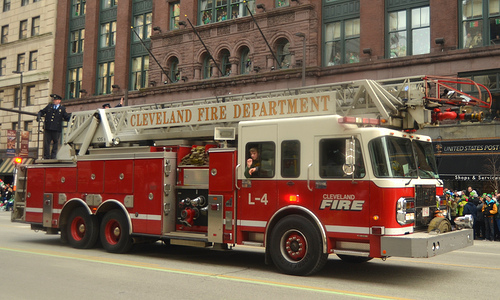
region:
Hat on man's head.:
[48, 84, 81, 133]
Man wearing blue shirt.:
[48, 101, 65, 113]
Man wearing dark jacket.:
[36, 102, 93, 144]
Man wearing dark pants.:
[34, 135, 62, 152]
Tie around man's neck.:
[47, 95, 69, 117]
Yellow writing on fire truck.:
[125, 99, 364, 129]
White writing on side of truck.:
[241, 185, 387, 217]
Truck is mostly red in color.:
[51, 151, 382, 260]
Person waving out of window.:
[228, 137, 265, 174]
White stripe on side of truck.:
[25, 198, 372, 247]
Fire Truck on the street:
[6, 80, 466, 283]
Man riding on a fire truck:
[39, 85, 64, 160]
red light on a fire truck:
[273, 183, 306, 210]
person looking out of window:
[239, 150, 269, 182]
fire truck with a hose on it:
[422, 195, 449, 245]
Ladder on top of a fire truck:
[68, 88, 445, 144]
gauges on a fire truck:
[163, 184, 222, 239]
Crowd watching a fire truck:
[453, 179, 498, 254]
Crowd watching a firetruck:
[433, 155, 490, 239]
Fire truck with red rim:
[272, 215, 334, 277]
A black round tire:
[266, 213, 327, 279]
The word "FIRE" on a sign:
[194, 101, 229, 128]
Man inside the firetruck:
[235, 138, 270, 183]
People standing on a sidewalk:
[448, 183, 498, 243]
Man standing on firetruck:
[33, 88, 74, 163]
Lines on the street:
[1, 239, 410, 298]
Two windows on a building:
[319, 3, 431, 72]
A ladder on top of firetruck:
[58, 75, 407, 146]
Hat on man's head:
[46, 88, 66, 105]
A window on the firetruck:
[277, 135, 305, 182]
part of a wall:
[443, 242, 448, 247]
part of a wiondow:
[306, 143, 328, 165]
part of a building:
[363, 32, 381, 47]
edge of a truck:
[376, 155, 392, 182]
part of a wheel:
[284, 210, 291, 235]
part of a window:
[412, 44, 421, 61]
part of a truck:
[364, 153, 373, 163]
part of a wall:
[471, 127, 477, 142]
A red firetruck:
[12, 65, 480, 282]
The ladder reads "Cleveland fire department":
[132, 90, 333, 127]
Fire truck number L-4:
[245, 187, 275, 213]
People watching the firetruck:
[439, 180, 499, 223]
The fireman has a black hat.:
[49, 90, 62, 102]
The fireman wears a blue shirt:
[50, 103, 62, 110]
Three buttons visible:
[50, 110, 57, 124]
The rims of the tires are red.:
[52, 185, 335, 278]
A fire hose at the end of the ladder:
[434, 103, 496, 130]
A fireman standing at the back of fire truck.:
[32, 88, 69, 161]